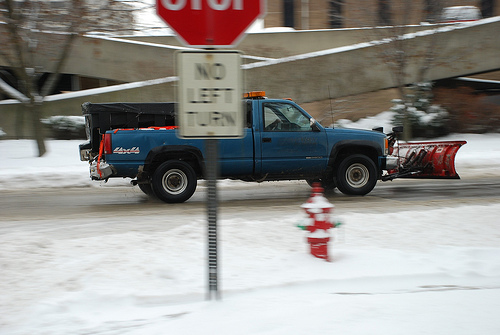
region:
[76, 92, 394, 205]
Blue truck traveling down street.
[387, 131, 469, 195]
Red snow plow in front of truck.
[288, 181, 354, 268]
Red fire hydrant on sidewalk.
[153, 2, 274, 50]
Bottom part of a red stop sign.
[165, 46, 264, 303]
A black and white traffic sign.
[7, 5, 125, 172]
Tree growing next to sidewalk.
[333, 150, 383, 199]
Front right tire on blue truck.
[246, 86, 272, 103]
Orange lights on roof of blue truck.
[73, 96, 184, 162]
Black bends on back of blue truck.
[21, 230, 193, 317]
Snow packed on side of street.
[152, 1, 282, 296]
a stop sign at the side of a street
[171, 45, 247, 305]
a no left turn sign at the side of the road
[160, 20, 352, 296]
a red fire hydrant in a snow bank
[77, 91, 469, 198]
a snow plow truck passing by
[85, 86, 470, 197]
a blue pick up truck with a red snow plow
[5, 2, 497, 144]
cement ramps in the background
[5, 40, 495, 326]
a winter snowstorm has covered the area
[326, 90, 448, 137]
snow accumulated on bushes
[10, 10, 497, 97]
snow has accumulated on the ramps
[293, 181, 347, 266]
the fire hydrant has green plugs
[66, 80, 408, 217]
blue pickup truck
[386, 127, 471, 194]
red snow plow shovel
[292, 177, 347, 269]
red fire hydrant covered in white snow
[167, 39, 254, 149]
white and black traffic sign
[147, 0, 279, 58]
bottom of a red and white stop sign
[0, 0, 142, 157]
brown leafless tree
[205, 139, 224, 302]
metal sign post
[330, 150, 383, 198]
black truck tire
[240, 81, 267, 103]
orange vehicle light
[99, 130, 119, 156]
red tail light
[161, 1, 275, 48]
a red stop sign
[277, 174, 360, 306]
a red fire hydrant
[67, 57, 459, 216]
a blue truck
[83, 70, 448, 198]
a blue plow truck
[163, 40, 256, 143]
no left turn sign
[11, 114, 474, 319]
snow on the ground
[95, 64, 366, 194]
a 4x4 blue truck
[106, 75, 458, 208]
a 4x4 blue plow truck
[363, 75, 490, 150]
bushes and trees with snow on them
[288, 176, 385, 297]
a red fire hydrant with snow on it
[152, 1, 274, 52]
the sign is red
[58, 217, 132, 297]
the snow is white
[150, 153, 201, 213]
the tire is black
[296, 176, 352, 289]
the hydrant is red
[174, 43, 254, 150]
the sign is white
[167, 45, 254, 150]
the sign says no left time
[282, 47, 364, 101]
the wall is gray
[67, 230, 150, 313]
the snow is thin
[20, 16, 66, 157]
the tree is brown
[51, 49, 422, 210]
the truck is blue